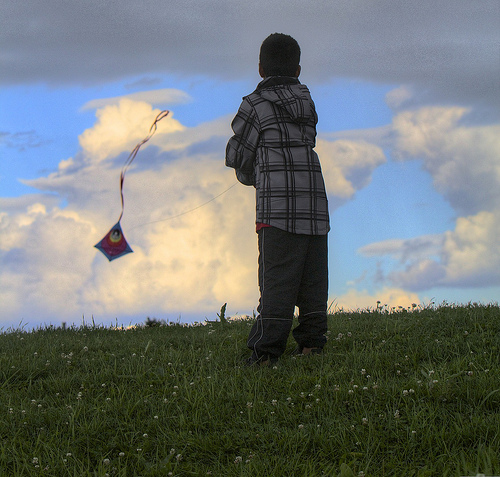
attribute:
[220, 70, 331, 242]
jacket — plaid, grey 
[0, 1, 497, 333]
sky — blue 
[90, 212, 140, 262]
kite — multi colored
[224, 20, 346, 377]
boy — little 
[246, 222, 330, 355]
jeans — black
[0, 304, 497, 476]
hillside — grassy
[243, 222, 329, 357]
pants — black 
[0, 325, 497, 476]
flowers — White